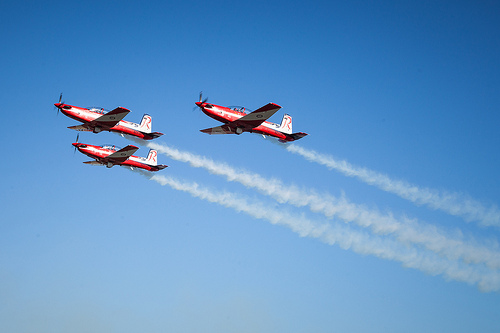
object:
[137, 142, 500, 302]
smoke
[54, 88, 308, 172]
planes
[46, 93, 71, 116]
propellers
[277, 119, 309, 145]
tails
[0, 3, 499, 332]
sky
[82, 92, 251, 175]
pilots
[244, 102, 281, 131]
wings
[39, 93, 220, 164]
nose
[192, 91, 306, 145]
plane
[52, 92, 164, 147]
plane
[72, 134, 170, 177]
plane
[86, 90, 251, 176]
glass